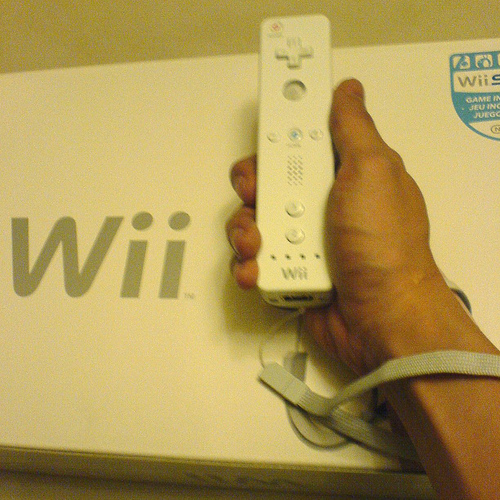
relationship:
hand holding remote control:
[224, 76, 499, 499] [253, 12, 354, 310]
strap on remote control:
[254, 306, 499, 470] [253, 12, 354, 310]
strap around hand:
[254, 306, 499, 470] [224, 76, 499, 499]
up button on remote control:
[285, 33, 303, 45] [253, 12, 354, 310]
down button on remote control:
[283, 57, 305, 70] [253, 12, 354, 310]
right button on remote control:
[303, 47, 315, 59] [253, 12, 354, 310]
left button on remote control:
[275, 45, 288, 60] [253, 12, 354, 310]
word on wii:
[4, 204, 200, 309] [0, 31, 499, 497]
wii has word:
[0, 31, 499, 497] [4, 204, 200, 309]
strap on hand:
[254, 306, 499, 470] [224, 76, 499, 499]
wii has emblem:
[0, 31, 499, 497] [447, 49, 499, 146]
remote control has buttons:
[253, 12, 354, 310] [281, 194, 310, 247]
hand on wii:
[224, 76, 499, 499] [0, 31, 499, 497]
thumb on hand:
[324, 72, 389, 158] [224, 76, 499, 499]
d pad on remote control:
[273, 35, 316, 71] [253, 12, 354, 310]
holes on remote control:
[283, 153, 309, 187] [253, 12, 354, 310]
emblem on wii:
[447, 49, 499, 146] [0, 31, 499, 497]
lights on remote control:
[267, 248, 325, 263] [253, 12, 354, 310]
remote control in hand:
[253, 12, 354, 310] [224, 76, 499, 499]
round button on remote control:
[281, 76, 310, 103] [253, 12, 354, 310]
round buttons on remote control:
[265, 126, 325, 144] [253, 12, 354, 310]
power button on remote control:
[265, 17, 286, 36] [253, 12, 354, 310]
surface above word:
[7, 76, 213, 194] [4, 204, 200, 309]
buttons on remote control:
[281, 194, 310, 247] [253, 12, 354, 310]